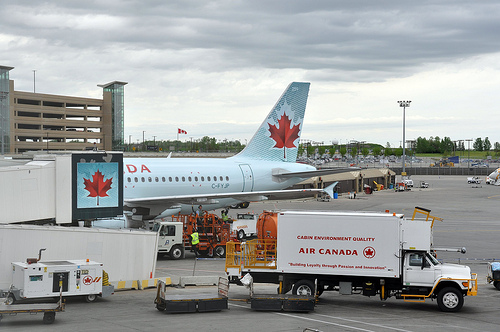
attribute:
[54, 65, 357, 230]
plane — maple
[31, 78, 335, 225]
airplane — white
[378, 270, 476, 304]
bars — yellow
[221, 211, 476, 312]
truck — white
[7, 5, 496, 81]
sky — cloudy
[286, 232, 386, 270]
lettering — red 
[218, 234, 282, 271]
railing — yellow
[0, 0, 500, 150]
skies — cloudy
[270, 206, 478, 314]
truck — white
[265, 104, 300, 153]
leaf — red